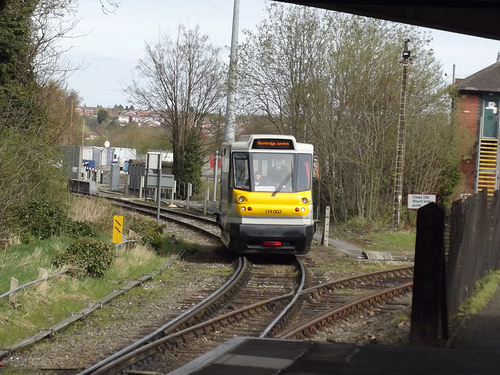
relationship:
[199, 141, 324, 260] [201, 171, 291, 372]
train on track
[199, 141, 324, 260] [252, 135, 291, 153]
train displays some lettering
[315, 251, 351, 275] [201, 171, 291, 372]
grass next to track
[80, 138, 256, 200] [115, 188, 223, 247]
building behind tracks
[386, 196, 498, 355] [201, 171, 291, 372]
fence next to track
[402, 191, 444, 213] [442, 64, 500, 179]
sign next to building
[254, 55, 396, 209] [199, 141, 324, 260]
trees are behind train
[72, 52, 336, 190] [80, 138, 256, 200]
background shows some buildings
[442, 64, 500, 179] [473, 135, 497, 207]
building has some stairs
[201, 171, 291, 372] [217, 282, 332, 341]
track has a line junction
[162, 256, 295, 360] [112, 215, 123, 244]
junction has a sign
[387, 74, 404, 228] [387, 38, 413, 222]
ladder up against a utility pole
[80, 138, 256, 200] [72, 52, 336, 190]
buildings are in distance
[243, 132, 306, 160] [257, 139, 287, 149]
sign indicates destination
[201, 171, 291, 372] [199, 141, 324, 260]
track has on it a train engine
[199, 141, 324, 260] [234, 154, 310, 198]
train has a windshield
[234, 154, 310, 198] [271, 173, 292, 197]
windshield has windshield wiper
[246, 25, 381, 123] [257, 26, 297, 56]
branches have no leaves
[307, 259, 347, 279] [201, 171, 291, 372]
gravel in between track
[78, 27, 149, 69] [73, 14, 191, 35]
sky has cloud cover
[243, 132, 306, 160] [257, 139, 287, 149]
sign to inform of destination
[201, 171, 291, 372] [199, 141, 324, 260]
track are for train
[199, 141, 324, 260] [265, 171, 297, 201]
train has windshield wiper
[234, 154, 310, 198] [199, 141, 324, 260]
windshield on train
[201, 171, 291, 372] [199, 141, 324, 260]
track for train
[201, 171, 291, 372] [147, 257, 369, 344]
track are on ground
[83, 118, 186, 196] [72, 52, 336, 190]
buildings are in background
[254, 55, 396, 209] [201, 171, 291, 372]
trees are alongside track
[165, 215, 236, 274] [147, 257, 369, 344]
shadow cast on ground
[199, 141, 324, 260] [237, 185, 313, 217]
train has lights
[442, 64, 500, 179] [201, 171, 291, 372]
building alongside track